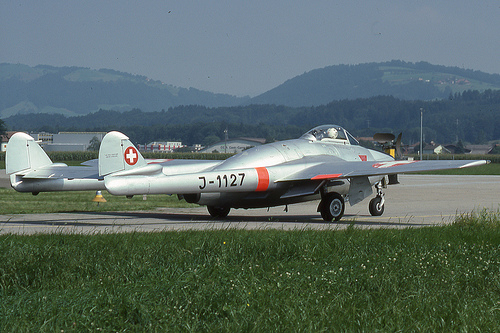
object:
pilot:
[327, 126, 338, 138]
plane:
[0, 126, 483, 220]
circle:
[122, 146, 140, 166]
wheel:
[319, 192, 345, 221]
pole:
[419, 107, 423, 160]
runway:
[411, 192, 448, 211]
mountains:
[137, 84, 195, 113]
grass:
[381, 259, 438, 286]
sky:
[208, 16, 255, 42]